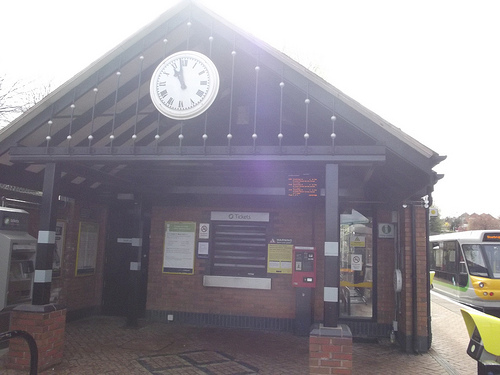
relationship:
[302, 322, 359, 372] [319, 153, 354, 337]
bricks on post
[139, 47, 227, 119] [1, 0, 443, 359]
clock on building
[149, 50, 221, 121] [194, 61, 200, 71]
clock has roman numeral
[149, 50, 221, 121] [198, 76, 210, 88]
clock has roman numeral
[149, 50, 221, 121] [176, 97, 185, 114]
clock has roman numeral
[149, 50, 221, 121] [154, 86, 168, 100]
clock has roman numeral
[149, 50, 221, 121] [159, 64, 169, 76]
clock has roman numeral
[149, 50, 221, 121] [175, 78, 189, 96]
clock has circle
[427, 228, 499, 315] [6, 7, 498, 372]
train at station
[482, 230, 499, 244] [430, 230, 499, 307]
sign on train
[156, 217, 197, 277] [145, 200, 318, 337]
sign on wall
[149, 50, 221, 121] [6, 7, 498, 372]
clock of a station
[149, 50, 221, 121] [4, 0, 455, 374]
clock of a train station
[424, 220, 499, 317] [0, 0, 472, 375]
train at railway station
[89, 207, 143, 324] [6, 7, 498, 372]
doorway at station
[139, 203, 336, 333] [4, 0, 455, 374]
counter at train station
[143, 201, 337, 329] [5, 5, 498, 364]
counter at railway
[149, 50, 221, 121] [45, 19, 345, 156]
clock on bars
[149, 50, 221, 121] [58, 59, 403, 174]
clock on building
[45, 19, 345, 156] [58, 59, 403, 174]
bars of a building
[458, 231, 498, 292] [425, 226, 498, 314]
head of a train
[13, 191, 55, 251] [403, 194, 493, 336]
window of a train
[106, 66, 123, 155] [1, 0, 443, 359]
metal bar on building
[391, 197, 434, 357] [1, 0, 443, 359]
brick pillar of building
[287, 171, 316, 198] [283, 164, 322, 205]
words on screen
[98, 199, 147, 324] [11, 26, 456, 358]
door on building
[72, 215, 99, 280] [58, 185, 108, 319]
sign on wall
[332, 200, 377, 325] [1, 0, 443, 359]
glass door on building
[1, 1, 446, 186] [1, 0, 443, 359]
roof of building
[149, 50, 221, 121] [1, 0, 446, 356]
clock at terminal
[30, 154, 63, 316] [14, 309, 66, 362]
poles supported by brick